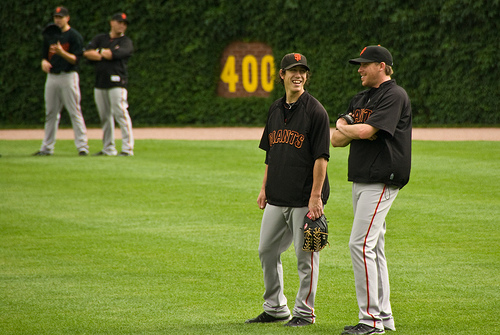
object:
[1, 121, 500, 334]
field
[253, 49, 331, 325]
boy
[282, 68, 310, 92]
face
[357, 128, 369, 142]
elbow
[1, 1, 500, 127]
fence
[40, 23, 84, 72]
jersey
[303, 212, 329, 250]
glove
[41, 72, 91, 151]
trousers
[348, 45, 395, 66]
cap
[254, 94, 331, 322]
uniform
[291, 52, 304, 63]
logo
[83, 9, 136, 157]
man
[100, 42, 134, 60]
arms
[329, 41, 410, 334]
players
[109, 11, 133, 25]
cap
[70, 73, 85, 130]
stripe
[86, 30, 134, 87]
shirt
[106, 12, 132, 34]
head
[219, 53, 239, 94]
number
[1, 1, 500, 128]
ivy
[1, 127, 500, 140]
warning track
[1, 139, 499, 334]
grass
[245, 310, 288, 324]
shoes